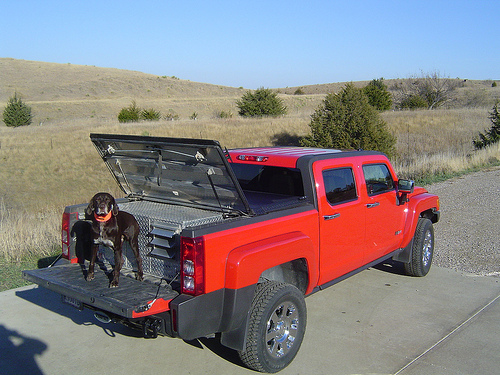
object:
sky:
[0, 0, 499, 91]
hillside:
[0, 65, 255, 126]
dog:
[84, 190, 146, 289]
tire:
[236, 279, 308, 375]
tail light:
[59, 241, 71, 258]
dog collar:
[92, 208, 112, 223]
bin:
[95, 199, 224, 284]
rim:
[264, 298, 299, 360]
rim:
[420, 226, 434, 268]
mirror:
[392, 176, 415, 194]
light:
[181, 275, 196, 297]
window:
[320, 164, 358, 206]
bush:
[0, 91, 36, 129]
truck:
[20, 131, 442, 375]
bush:
[0, 89, 33, 139]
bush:
[232, 83, 291, 117]